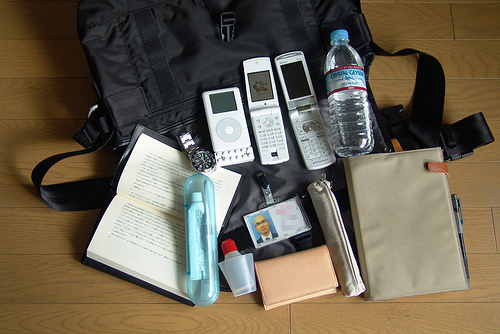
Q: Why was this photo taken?
A: To show the contents of a briefcase.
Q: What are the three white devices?
A: Electronics.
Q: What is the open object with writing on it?
A: A book.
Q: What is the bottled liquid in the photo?
A: Water.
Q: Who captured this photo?
A: A photographer.